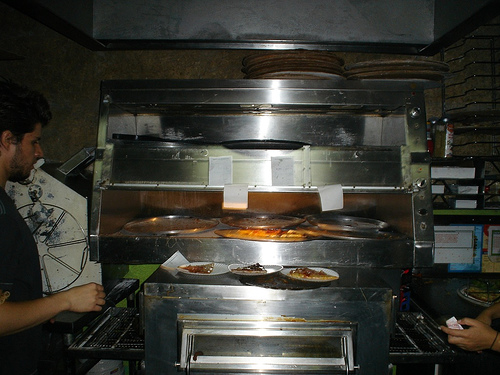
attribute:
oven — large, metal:
[55, 81, 435, 298]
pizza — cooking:
[212, 226, 321, 244]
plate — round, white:
[176, 260, 233, 278]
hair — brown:
[0, 81, 51, 142]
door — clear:
[180, 317, 352, 371]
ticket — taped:
[364, 112, 385, 147]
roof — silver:
[101, 76, 425, 109]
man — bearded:
[0, 79, 105, 374]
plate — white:
[228, 261, 285, 280]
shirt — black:
[0, 188, 44, 373]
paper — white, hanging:
[220, 183, 250, 212]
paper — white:
[5, 160, 104, 298]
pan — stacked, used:
[259, 66, 346, 80]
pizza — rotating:
[223, 212, 302, 228]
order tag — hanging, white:
[270, 155, 296, 186]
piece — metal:
[124, 213, 223, 235]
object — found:
[343, 58, 449, 66]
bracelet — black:
[489, 326, 498, 352]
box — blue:
[441, 221, 484, 272]